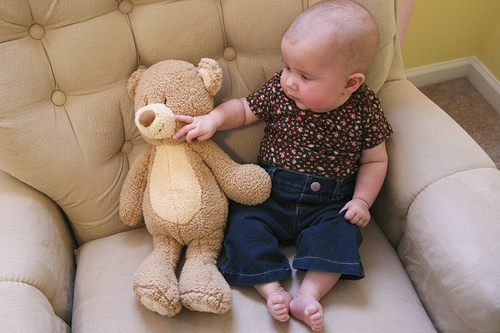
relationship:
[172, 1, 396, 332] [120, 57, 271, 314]
baby touching bear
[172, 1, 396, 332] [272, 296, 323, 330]
baby curling toes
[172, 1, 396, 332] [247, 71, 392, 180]
baby wearing shirt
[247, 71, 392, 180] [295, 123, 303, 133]
shirt has flowers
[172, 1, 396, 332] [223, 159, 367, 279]
baby wearing jeans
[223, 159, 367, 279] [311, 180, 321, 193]
jeans have a button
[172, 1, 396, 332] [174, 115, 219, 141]
baby has hand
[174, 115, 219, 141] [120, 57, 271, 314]
hand on bear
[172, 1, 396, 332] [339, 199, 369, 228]
baby has hand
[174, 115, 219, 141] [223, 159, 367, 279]
hand holding jeans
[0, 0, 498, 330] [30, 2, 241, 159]
chair has buttons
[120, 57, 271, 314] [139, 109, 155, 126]
bear has nose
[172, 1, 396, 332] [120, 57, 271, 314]
baby near bear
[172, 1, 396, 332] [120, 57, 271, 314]
baby touching a bear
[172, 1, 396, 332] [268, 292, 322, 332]
baby has feet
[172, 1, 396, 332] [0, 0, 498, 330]
baby in chair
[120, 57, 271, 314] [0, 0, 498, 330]
bear in chair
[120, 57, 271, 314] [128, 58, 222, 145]
bear has head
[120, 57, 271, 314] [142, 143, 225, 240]
bear has tummy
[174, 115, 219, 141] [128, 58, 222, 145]
hand touching head